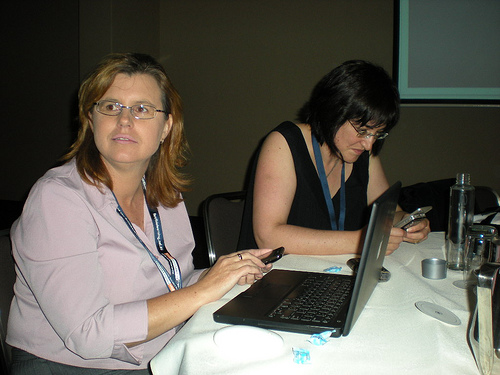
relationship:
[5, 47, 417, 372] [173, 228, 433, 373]
woman sitting at table